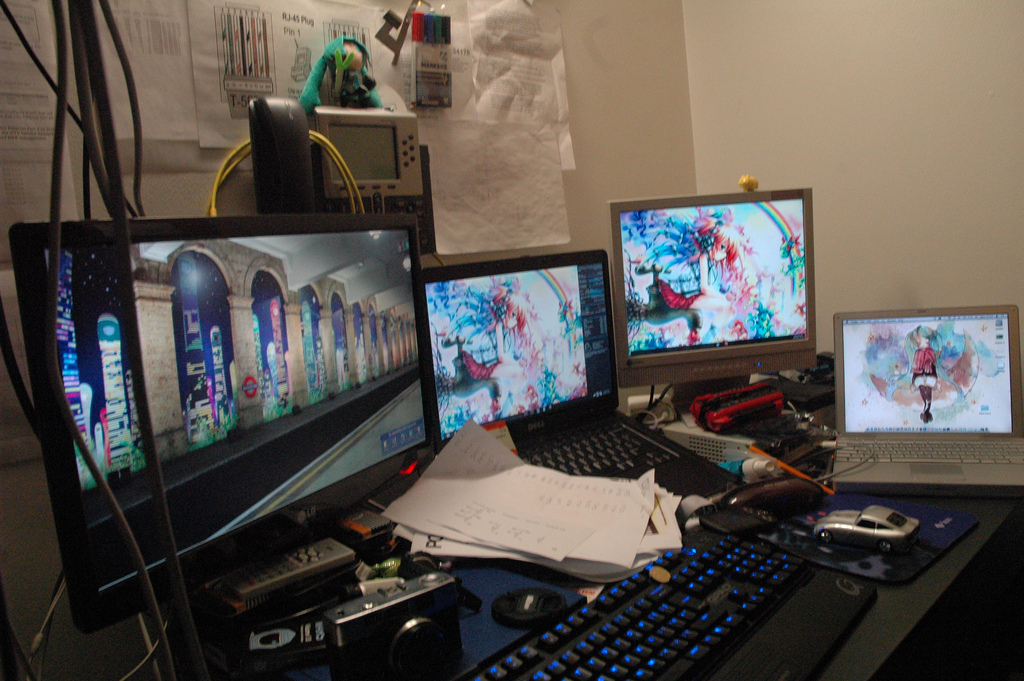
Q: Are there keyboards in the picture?
A: Yes, there is a keyboard.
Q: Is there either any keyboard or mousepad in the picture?
A: Yes, there is a keyboard.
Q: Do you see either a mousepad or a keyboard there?
A: Yes, there is a keyboard.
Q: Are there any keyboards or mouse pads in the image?
A: Yes, there is a keyboard.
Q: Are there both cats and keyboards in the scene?
A: No, there is a keyboard but no cats.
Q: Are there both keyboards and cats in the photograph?
A: No, there is a keyboard but no cats.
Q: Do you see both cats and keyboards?
A: No, there is a keyboard but no cats.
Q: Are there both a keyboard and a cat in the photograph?
A: No, there is a keyboard but no cats.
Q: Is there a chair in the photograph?
A: No, there are no chairs.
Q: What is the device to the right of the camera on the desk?
A: The device is a keyboard.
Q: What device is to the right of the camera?
A: The device is a keyboard.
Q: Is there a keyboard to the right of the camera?
A: Yes, there is a keyboard to the right of the camera.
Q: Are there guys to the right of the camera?
A: No, there is a keyboard to the right of the camera.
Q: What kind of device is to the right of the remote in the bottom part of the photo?
A: The device is a keyboard.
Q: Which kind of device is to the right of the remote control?
A: The device is a keyboard.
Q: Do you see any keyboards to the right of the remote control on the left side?
A: Yes, there is a keyboard to the right of the remote.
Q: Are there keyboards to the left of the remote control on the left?
A: No, the keyboard is to the right of the remote control.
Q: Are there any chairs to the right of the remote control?
A: No, there is a keyboard to the right of the remote control.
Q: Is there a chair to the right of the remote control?
A: No, there is a keyboard to the right of the remote control.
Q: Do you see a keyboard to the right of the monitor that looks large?
A: Yes, there is a keyboard to the right of the monitor.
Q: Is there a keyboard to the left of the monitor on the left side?
A: No, the keyboard is to the right of the monitor.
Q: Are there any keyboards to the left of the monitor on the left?
A: No, the keyboard is to the right of the monitor.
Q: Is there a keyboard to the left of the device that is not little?
A: No, the keyboard is to the right of the monitor.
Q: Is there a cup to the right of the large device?
A: No, there is a keyboard to the right of the monitor.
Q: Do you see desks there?
A: Yes, there is a desk.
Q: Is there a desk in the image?
A: Yes, there is a desk.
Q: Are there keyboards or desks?
A: Yes, there is a desk.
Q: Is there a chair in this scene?
A: No, there are no chairs.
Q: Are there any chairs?
A: No, there are no chairs.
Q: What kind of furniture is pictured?
A: The furniture is a desk.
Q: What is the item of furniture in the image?
A: The piece of furniture is a desk.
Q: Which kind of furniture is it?
A: The piece of furniture is a desk.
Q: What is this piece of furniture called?
A: That is a desk.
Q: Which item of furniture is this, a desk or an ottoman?
A: That is a desk.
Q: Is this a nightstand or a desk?
A: This is a desk.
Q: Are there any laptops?
A: Yes, there is a laptop.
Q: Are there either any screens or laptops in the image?
A: Yes, there is a laptop.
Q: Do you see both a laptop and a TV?
A: No, there is a laptop but no televisions.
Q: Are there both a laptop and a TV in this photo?
A: No, there is a laptop but no televisions.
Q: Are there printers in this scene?
A: No, there are no printers.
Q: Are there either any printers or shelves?
A: No, there are no printers or shelves.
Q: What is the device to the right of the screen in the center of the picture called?
A: The device is a laptop.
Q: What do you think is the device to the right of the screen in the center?
A: The device is a laptop.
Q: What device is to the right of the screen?
A: The device is a laptop.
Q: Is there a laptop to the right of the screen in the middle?
A: Yes, there is a laptop to the right of the screen.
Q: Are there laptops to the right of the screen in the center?
A: Yes, there is a laptop to the right of the screen.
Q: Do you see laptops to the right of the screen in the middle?
A: Yes, there is a laptop to the right of the screen.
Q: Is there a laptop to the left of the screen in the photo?
A: No, the laptop is to the right of the screen.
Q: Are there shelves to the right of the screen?
A: No, there is a laptop to the right of the screen.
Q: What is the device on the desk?
A: The device is a laptop.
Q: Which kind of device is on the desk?
A: The device is a laptop.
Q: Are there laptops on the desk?
A: Yes, there is a laptop on the desk.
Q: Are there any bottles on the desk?
A: No, there is a laptop on the desk.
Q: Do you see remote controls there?
A: Yes, there is a remote control.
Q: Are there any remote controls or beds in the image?
A: Yes, there is a remote control.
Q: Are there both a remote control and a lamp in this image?
A: No, there is a remote control but no lamps.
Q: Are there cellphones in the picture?
A: No, there are no cellphones.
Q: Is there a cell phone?
A: No, there are no cell phones.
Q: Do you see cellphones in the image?
A: No, there are no cellphones.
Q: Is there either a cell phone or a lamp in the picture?
A: No, there are no cell phones or lamps.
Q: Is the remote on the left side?
A: Yes, the remote is on the left of the image.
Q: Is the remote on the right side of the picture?
A: No, the remote is on the left of the image.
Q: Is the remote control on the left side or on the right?
A: The remote control is on the left of the image.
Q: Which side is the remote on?
A: The remote is on the left of the image.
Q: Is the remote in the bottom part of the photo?
A: Yes, the remote is in the bottom of the image.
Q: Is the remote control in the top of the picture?
A: No, the remote control is in the bottom of the image.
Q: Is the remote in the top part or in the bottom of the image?
A: The remote is in the bottom of the image.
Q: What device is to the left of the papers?
A: The device is a remote control.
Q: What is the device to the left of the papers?
A: The device is a remote control.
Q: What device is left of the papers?
A: The device is a remote control.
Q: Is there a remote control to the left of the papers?
A: Yes, there is a remote control to the left of the papers.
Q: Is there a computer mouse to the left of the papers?
A: No, there is a remote control to the left of the papers.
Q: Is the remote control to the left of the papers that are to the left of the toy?
A: Yes, the remote control is to the left of the papers.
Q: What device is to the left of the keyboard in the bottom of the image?
A: The device is a remote control.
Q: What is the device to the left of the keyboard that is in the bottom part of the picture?
A: The device is a remote control.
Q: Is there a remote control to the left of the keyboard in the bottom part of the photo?
A: Yes, there is a remote control to the left of the keyboard.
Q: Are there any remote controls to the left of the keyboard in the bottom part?
A: Yes, there is a remote control to the left of the keyboard.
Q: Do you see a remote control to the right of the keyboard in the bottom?
A: No, the remote control is to the left of the keyboard.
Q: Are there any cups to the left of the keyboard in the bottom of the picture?
A: No, there is a remote control to the left of the keyboard.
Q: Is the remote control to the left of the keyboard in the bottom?
A: Yes, the remote control is to the left of the keyboard.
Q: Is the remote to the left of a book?
A: No, the remote is to the left of the keyboard.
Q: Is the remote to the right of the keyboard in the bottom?
A: No, the remote is to the left of the keyboard.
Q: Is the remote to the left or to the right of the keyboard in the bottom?
A: The remote is to the left of the keyboard.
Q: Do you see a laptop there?
A: Yes, there is a laptop.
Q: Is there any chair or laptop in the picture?
A: Yes, there is a laptop.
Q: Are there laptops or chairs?
A: Yes, there is a laptop.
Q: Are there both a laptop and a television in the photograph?
A: No, there is a laptop but no televisions.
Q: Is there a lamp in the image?
A: No, there are no lamps.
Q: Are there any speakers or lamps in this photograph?
A: No, there are no lamps or speakers.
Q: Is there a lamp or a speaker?
A: No, there are no lamps or speakers.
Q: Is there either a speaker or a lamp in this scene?
A: No, there are no lamps or speakers.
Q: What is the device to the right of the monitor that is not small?
A: The device is a laptop.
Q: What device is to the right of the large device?
A: The device is a laptop.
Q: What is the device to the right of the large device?
A: The device is a laptop.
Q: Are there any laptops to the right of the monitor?
A: Yes, there is a laptop to the right of the monitor.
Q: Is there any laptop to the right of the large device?
A: Yes, there is a laptop to the right of the monitor.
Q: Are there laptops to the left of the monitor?
A: No, the laptop is to the right of the monitor.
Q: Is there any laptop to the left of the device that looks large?
A: No, the laptop is to the right of the monitor.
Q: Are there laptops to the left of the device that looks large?
A: No, the laptop is to the right of the monitor.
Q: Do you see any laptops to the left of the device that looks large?
A: No, the laptop is to the right of the monitor.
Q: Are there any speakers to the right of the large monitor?
A: No, there is a laptop to the right of the monitor.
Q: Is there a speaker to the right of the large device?
A: No, there is a laptop to the right of the monitor.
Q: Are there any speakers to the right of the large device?
A: No, there is a laptop to the right of the monitor.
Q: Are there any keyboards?
A: Yes, there is a keyboard.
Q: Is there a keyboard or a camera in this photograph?
A: Yes, there is a keyboard.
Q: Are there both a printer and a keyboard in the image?
A: No, there is a keyboard but no printers.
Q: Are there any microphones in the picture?
A: No, there are no microphones.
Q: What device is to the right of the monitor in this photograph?
A: The device is a keyboard.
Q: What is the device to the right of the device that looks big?
A: The device is a keyboard.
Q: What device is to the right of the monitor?
A: The device is a keyboard.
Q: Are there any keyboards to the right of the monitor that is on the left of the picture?
A: Yes, there is a keyboard to the right of the monitor.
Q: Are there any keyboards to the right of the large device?
A: Yes, there is a keyboard to the right of the monitor.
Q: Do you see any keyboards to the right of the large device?
A: Yes, there is a keyboard to the right of the monitor.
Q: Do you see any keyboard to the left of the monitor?
A: No, the keyboard is to the right of the monitor.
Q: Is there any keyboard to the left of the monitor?
A: No, the keyboard is to the right of the monitor.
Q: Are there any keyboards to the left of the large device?
A: No, the keyboard is to the right of the monitor.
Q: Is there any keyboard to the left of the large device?
A: No, the keyboard is to the right of the monitor.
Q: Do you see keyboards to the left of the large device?
A: No, the keyboard is to the right of the monitor.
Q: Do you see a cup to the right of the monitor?
A: No, there is a keyboard to the right of the monitor.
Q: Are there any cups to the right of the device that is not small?
A: No, there is a keyboard to the right of the monitor.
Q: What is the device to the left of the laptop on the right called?
A: The device is a keyboard.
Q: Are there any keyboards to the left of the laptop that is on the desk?
A: Yes, there is a keyboard to the left of the laptop computer.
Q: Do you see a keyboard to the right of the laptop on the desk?
A: No, the keyboard is to the left of the laptop.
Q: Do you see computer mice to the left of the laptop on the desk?
A: No, there is a keyboard to the left of the laptop.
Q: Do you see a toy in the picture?
A: Yes, there is a toy.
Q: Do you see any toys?
A: Yes, there is a toy.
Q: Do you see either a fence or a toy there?
A: Yes, there is a toy.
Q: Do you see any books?
A: No, there are no books.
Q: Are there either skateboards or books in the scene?
A: No, there are no books or skateboards.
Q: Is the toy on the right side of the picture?
A: Yes, the toy is on the right of the image.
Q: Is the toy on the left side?
A: No, the toy is on the right of the image.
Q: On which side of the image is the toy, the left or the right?
A: The toy is on the right of the image.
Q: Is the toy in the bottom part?
A: Yes, the toy is in the bottom of the image.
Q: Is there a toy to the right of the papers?
A: Yes, there is a toy to the right of the papers.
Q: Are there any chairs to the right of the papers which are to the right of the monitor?
A: No, there is a toy to the right of the papers.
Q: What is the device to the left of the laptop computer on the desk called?
A: The device is a screen.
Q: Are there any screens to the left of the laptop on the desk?
A: Yes, there is a screen to the left of the laptop.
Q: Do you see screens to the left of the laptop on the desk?
A: Yes, there is a screen to the left of the laptop.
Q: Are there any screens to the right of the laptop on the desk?
A: No, the screen is to the left of the laptop.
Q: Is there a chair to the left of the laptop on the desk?
A: No, there is a screen to the left of the laptop computer.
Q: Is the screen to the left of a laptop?
A: Yes, the screen is to the left of a laptop.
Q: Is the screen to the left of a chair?
A: No, the screen is to the left of a laptop.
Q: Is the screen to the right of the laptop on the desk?
A: No, the screen is to the left of the laptop.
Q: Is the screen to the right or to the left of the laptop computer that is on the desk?
A: The screen is to the left of the laptop computer.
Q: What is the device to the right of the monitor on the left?
A: The device is a screen.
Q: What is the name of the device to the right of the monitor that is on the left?
A: The device is a screen.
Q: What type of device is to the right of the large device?
A: The device is a screen.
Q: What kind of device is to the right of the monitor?
A: The device is a screen.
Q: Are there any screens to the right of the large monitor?
A: Yes, there is a screen to the right of the monitor.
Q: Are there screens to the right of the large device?
A: Yes, there is a screen to the right of the monitor.